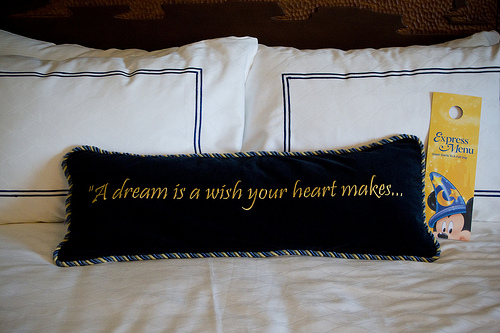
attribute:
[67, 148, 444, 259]
pillow — blue, long, black, gold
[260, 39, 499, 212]
pillow — white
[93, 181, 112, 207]
letter — golden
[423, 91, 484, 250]
card — for customers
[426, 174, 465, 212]
hat — purple, wizard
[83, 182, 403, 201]
lettering — gold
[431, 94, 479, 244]
bag — yellow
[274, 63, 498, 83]
trim — blue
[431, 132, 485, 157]
letters — blue, written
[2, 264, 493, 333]
blanket — white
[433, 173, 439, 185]
stars — gold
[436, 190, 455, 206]
moons — gold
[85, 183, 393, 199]
letters — gold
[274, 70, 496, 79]
lines — blue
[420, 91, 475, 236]
door hanger — yellow, blue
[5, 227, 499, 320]
comforter — white